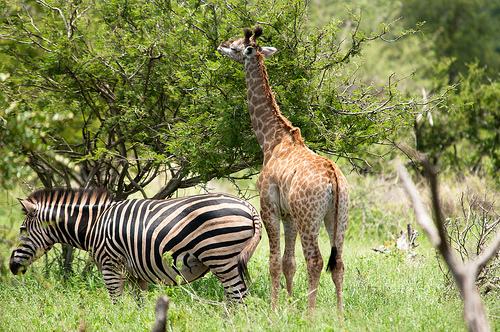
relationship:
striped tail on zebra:
[242, 204, 263, 281] [7, 159, 279, 312]